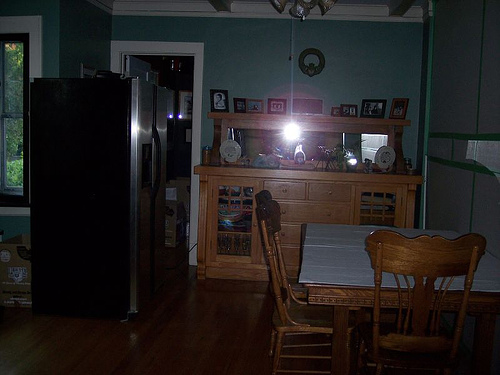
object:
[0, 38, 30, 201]
window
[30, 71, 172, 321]
refrigerator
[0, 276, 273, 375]
floors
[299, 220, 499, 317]
table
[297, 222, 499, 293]
cloth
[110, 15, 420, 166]
wall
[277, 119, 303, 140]
light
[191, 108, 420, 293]
hutch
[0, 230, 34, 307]
box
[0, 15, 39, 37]
trim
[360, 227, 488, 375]
chair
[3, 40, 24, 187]
trees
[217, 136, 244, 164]
plate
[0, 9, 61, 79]
wall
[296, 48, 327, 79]
wreath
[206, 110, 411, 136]
shelf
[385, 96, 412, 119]
picture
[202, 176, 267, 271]
door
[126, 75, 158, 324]
doors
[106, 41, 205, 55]
trim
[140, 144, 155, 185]
handle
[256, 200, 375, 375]
chairs